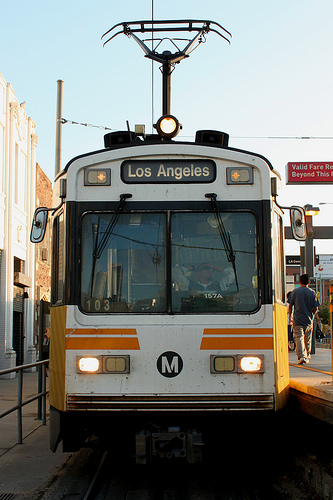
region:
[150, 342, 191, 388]
An M on a bus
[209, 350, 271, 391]
Headlights on a bus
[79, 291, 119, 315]
The number 103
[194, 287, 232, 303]
Letters and numbers saying 157A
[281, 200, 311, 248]
A bus's side window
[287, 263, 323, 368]
A man on a sidwalk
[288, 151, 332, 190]
A sign saying fare is required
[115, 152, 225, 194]
A bus sign that says Los Angeles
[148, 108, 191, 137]
A light on the top of a bus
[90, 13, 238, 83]
Electrical conducts on the top of a bus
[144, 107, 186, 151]
light on top of train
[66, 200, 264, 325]
front window of train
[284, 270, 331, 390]
man walking on train platform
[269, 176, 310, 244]
left rear view mirror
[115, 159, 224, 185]
train destination sign reading los angeles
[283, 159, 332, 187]
valid fare rider sign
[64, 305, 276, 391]
orange and white front of train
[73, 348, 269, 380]
head lights in on position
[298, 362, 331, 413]
yellow stripe on platform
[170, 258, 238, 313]
train driver leaning back in seat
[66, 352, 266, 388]
the light is on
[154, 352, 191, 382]
the circle is black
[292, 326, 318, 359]
the pants are brown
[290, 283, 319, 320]
the shirt is blue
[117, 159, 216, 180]
the traain is headed to losangeles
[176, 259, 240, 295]
the conductor is in the train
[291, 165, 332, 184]
the ssign is red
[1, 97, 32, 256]
the building is white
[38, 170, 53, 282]
the building is brown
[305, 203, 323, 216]
the light is on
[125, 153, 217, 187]
LOS ANGELES ON BUS TITLE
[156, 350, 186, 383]
M LOGO IN CENTER OF TRAIN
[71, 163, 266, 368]
COMMUTER TRAIN IN URBAN SETTING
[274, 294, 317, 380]
SUN REFLECTING OFF TRAIN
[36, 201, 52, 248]
MIRROR ON SIDE OF TRAIN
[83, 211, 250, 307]
FRONT WINDOW OF TRAIN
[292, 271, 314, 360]
PASSENGER ON SIDE OF TRAIN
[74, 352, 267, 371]
HEADLIGHTS ON FRONT OF TRAIN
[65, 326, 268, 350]
ORANGE STRIPED ON TRAIN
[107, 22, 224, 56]
ELECTRIC CONDUCTER ON TRAIN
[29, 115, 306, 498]
white and orange train on the railroad tracks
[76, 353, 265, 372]
two head lights on the front of train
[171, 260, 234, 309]
conductor on the train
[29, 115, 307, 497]
Los Angeles on the front of train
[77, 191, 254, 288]
black window shield wipers on the front of train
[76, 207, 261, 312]
the train's front windows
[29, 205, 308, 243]
two rear view mirrors on side of the train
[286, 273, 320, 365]
man walking beside the train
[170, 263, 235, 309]
man sitting on the driver side of train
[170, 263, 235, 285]
man's hands resting on the head